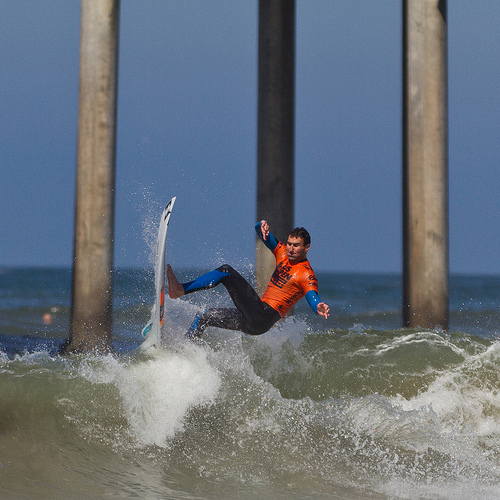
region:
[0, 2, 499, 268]
A blue sky.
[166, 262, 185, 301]
A man's left foot.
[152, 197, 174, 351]
A mostly white surfboard.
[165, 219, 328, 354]
A man in orange, black and blue.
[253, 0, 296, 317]
Darkest concrete pillar.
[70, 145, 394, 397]
this is a man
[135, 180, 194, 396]
the surfboard is white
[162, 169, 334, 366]
man wearing a wet suit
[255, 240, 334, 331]
orange top of suit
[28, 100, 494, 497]
man is riding a surfboard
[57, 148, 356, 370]
the man is sideways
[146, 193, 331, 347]
Man in an orange shirt riding a surf board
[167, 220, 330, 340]
Man in black wet suit wearing an orange shirt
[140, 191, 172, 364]
White surf board with orange trim in water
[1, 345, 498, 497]
Waves in the water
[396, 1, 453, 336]
Wooden pole in the water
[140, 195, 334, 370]
Man falling off white surf board into water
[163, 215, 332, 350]
Man in orange shirt wearing black wet suit with blue trim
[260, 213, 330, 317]
Man wearing an orange shirt with black lettering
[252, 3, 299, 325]
Wooden pole in water behind the man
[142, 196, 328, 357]
Surfer falling sideways in the water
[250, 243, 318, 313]
A wet orange shirt on a surfer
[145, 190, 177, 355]
A white surfboard in the air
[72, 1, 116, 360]
A cement post in an ocean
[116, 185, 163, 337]
A water splash over a wave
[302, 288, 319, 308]
A wet blue sleeve on a man's arm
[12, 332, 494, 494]
A large wave in the ocean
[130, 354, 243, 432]
Frothing water on a wave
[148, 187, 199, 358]
The surfboard is straight up.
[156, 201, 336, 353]
The man is surfing.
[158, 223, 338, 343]
He is wearing a wet suit.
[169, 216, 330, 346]
The wet suit is orange, blue, and black.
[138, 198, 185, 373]
The surfboard is white with orange.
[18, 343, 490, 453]
Wvaes are in the water.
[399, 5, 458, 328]
The posts are wood.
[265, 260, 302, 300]
Writiing in on the shirt.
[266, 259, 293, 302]
The writing is black.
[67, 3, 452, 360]
surfer between two gray poles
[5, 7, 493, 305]
solid blue sky over dark ocean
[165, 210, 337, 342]
a man is surfing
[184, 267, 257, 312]
leg of a man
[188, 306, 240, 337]
leg of a man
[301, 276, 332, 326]
arm of a man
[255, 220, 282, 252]
arm of a man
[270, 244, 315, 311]
the shirt is orange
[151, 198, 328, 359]
man on the boar surf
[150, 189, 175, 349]
white surf board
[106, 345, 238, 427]
white foam of the ocean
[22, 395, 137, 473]
green ocean water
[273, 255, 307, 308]
orange and black shirt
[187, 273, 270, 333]
black and blue pant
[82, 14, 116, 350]
based gray dock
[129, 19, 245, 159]
clear blue sky behind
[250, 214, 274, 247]
right hand of the man over the sea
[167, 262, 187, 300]
lef foot to the man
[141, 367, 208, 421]
the water is white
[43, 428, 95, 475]
the water is brown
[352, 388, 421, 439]
a small wave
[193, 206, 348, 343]
a man surfing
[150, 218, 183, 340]
a surfboard